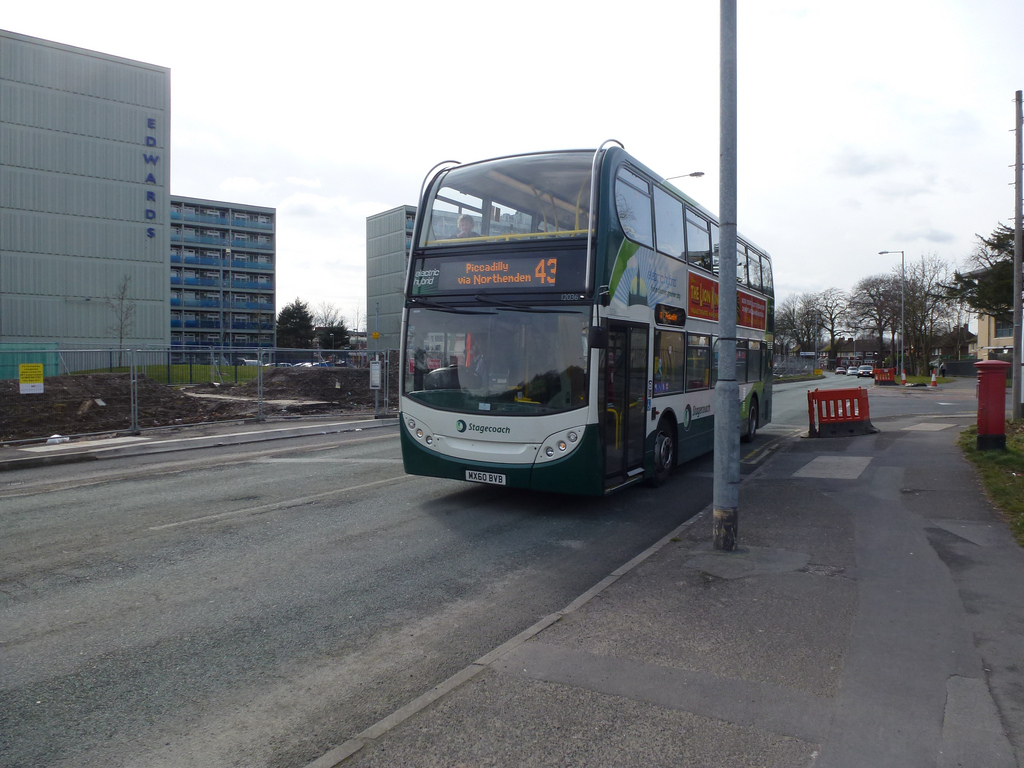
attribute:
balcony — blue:
[229, 209, 278, 226]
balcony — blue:
[175, 227, 229, 248]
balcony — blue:
[232, 231, 278, 244]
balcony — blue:
[179, 243, 224, 259]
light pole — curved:
[876, 244, 909, 377]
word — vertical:
[137, 105, 164, 252]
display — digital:
[424, 252, 568, 287]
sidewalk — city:
[326, 423, 1010, 766]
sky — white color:
[10, 0, 1023, 215]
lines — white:
[135, 457, 411, 531]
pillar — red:
[969, 351, 1015, 450]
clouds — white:
[206, 16, 701, 128]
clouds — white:
[748, 133, 1001, 247]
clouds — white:
[738, 10, 1015, 255]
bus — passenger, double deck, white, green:
[403, 129, 787, 512]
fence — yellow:
[12, 353, 48, 399]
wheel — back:
[735, 386, 770, 432]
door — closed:
[602, 318, 644, 478]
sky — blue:
[0, 7, 992, 373]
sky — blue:
[0, 11, 992, 327]